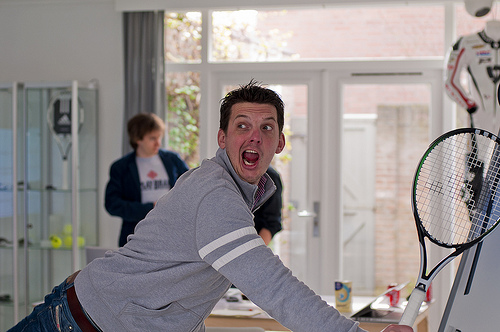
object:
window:
[159, 5, 495, 314]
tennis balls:
[63, 235, 84, 250]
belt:
[65, 270, 99, 331]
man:
[8, 76, 415, 331]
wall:
[2, 0, 118, 74]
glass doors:
[211, 69, 324, 296]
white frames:
[200, 60, 454, 303]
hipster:
[103, 110, 188, 247]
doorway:
[209, 71, 327, 294]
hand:
[377, 324, 415, 329]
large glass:
[339, 81, 436, 302]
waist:
[60, 269, 98, 332]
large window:
[204, 3, 443, 60]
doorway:
[331, 69, 442, 296]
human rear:
[218, 128, 225, 150]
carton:
[335, 281, 353, 312]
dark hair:
[218, 78, 285, 137]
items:
[49, 90, 87, 248]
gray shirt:
[71, 148, 369, 332]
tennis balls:
[48, 235, 63, 251]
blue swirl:
[336, 284, 349, 302]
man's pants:
[0, 276, 93, 330]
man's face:
[226, 110, 279, 182]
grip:
[398, 288, 425, 327]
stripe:
[196, 226, 266, 271]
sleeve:
[194, 185, 371, 332]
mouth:
[241, 149, 261, 169]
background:
[6, 16, 453, 221]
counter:
[203, 296, 432, 332]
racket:
[47, 90, 84, 190]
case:
[0, 77, 104, 332]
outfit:
[441, 30, 500, 222]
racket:
[398, 127, 499, 326]